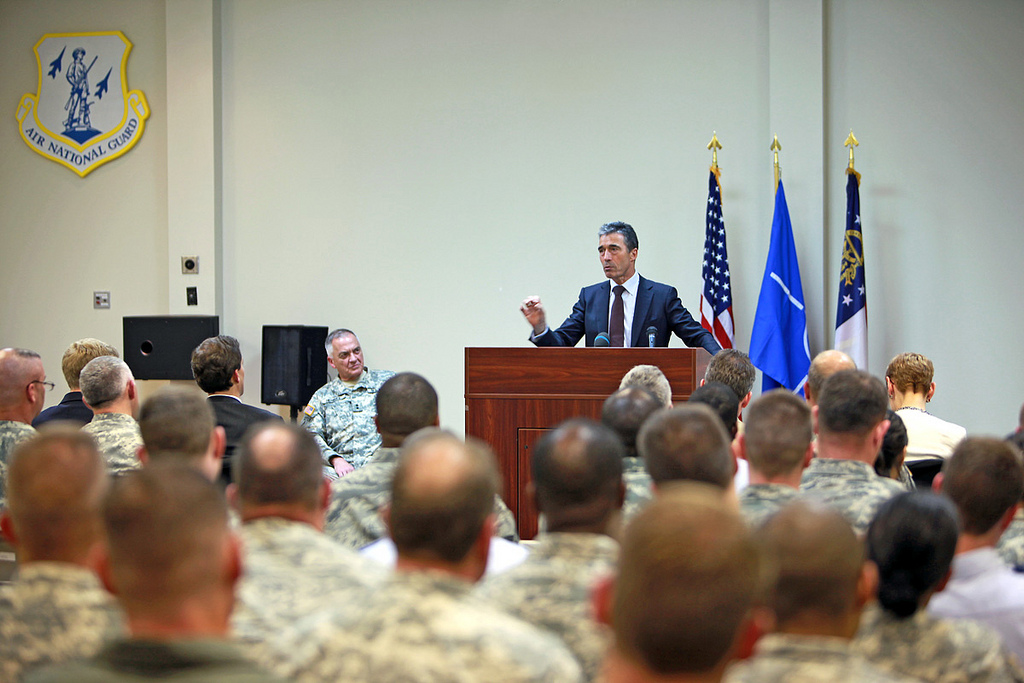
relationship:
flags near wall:
[696, 135, 893, 390] [172, 15, 1023, 380]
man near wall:
[487, 212, 725, 353] [172, 15, 1023, 380]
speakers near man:
[114, 306, 338, 416] [487, 212, 725, 353]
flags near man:
[696, 135, 893, 390] [487, 212, 725, 353]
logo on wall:
[6, 27, 179, 180] [172, 15, 1023, 380]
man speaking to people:
[487, 212, 725, 353] [28, 333, 1015, 653]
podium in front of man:
[455, 335, 750, 535] [487, 212, 725, 353]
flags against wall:
[696, 135, 893, 390] [172, 15, 1023, 380]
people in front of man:
[28, 333, 1015, 653] [487, 212, 725, 353]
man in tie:
[487, 212, 725, 353] [610, 281, 644, 345]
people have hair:
[28, 333, 1015, 653] [872, 506, 928, 621]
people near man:
[28, 333, 1015, 653] [487, 212, 725, 353]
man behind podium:
[487, 212, 725, 353] [455, 335, 750, 535]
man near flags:
[487, 212, 725, 353] [696, 135, 893, 390]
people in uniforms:
[28, 333, 1015, 653] [24, 564, 742, 671]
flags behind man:
[696, 135, 893, 390] [487, 212, 725, 353]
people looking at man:
[28, 333, 1015, 653] [487, 212, 725, 353]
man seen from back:
[380, 413, 614, 543] [2, 526, 1018, 674]